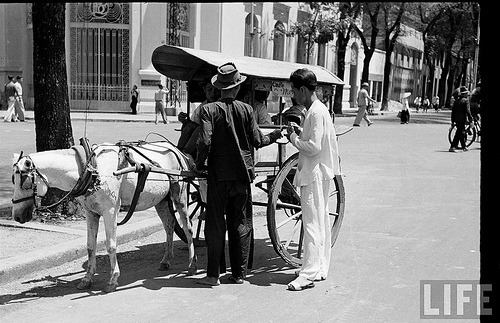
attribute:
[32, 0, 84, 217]
tree — brown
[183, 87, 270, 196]
shirt — black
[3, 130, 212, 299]
horse — white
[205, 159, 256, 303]
pants — black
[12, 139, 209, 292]
horse — white,  white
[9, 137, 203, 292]
white horse —  white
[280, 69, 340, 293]
man —  in suit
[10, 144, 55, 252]
head —  horse's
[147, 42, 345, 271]
cart —  two-wheeled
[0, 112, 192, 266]
horse —  white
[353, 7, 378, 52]
branches — tree's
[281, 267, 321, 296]
shoes — white 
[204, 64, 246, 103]
head — mans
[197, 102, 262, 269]
suit — black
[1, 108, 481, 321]
street — concrete